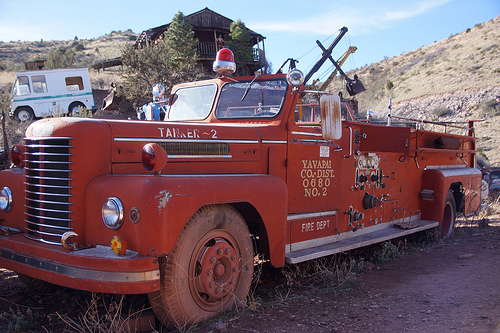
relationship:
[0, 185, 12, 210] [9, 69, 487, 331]
light of truck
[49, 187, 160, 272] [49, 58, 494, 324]
headlight on truck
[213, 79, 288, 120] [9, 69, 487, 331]
window on truck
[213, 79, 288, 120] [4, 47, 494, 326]
window on truck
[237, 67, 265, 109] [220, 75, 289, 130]
wipers on window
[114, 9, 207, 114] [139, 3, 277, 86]
tree next to house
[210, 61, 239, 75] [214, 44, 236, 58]
base of light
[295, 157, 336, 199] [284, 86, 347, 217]
writing on door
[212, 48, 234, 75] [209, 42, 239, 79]
base of light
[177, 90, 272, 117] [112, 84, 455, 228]
front screen of truck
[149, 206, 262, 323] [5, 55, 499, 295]
tire of truck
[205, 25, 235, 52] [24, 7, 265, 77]
person in building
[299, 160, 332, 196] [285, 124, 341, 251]
writing is on door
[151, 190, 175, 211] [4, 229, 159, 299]
scratch on bumper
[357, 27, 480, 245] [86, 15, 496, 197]
rocks are on hill